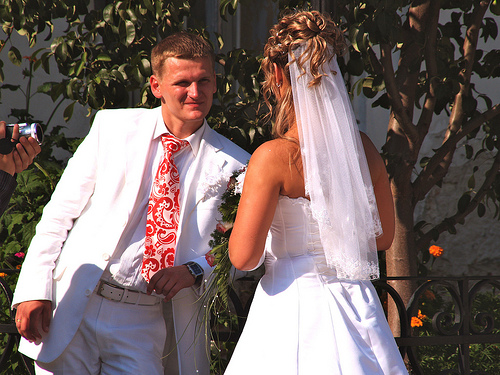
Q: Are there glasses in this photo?
A: No, there are no glasses.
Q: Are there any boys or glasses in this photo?
A: No, there are no glasses or boys.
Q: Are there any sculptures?
A: No, there are no sculptures.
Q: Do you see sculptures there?
A: No, there are no sculptures.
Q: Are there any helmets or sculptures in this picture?
A: No, there are no sculptures or helmets.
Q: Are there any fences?
A: Yes, there is a fence.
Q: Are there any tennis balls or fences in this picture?
A: Yes, there is a fence.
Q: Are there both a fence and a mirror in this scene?
A: No, there is a fence but no mirrors.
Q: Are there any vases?
A: No, there are no vases.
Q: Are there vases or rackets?
A: No, there are no vases or rackets.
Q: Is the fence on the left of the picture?
A: No, the fence is on the right of the image.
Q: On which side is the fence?
A: The fence is on the right of the image.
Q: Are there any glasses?
A: No, there are no glasses.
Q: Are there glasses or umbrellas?
A: No, there are no glasses or umbrellas.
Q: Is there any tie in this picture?
A: Yes, there is a tie.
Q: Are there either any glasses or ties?
A: Yes, there is a tie.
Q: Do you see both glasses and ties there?
A: No, there is a tie but no glasses.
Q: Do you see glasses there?
A: No, there are no glasses.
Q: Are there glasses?
A: No, there are no glasses.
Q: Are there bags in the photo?
A: No, there are no bags.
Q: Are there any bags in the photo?
A: No, there are no bags.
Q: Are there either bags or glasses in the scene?
A: No, there are no bags or glasses.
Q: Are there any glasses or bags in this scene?
A: No, there are no bags or glasses.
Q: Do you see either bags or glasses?
A: No, there are no bags or glasses.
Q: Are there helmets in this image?
A: No, there are no helmets.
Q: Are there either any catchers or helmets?
A: No, there are no helmets or catchers.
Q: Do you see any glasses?
A: No, there are no glasses.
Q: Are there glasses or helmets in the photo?
A: No, there are no glasses or helmets.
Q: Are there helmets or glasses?
A: No, there are no glasses or helmets.